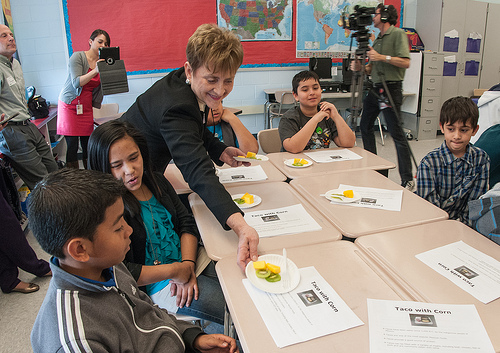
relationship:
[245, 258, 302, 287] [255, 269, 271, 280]
plate with kiwi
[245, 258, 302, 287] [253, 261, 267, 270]
plate with pineapple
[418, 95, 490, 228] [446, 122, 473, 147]
child has face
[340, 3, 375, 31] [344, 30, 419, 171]
camera sitting on tripod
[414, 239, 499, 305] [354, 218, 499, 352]
paper sitting on table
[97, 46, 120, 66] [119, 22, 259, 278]
ipad recording lady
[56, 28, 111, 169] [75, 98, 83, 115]
lady wearing name tag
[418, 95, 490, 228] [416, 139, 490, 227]
child wearing shirt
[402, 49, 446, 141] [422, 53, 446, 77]
cabinet with drawer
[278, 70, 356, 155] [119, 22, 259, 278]
kid smiling at lady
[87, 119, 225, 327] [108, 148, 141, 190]
girl has face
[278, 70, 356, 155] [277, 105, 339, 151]
kid wearing t-shirt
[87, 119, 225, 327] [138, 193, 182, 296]
girl wearing shirt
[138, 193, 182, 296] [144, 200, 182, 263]
shirt has trim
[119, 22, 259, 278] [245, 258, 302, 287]
lady handing plate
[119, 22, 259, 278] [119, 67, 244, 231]
lady wearing suit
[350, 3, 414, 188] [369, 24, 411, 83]
cameraman wearing shirt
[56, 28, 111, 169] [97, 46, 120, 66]
lady holding ipad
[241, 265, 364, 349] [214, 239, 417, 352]
paper sitting on table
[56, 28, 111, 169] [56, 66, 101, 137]
lady wearing dress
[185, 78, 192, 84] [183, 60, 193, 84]
earring hanging in ear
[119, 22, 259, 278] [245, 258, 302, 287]
lady serving plate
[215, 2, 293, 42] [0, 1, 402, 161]
wall map hanging on wall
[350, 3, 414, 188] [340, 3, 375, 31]
cameraman operating camera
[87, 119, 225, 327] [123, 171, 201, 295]
girl wearing sweater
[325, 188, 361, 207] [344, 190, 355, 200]
plate with pineapple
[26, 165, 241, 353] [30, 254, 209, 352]
boy wearing jacket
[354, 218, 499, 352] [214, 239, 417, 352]
table stuck to table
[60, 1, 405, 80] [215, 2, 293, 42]
board with wall map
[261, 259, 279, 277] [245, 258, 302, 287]
kiwi and pineapple on plate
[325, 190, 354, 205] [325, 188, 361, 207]
kiwi and pineapple on plate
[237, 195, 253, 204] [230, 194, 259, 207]
kiwi and pineapple on plate